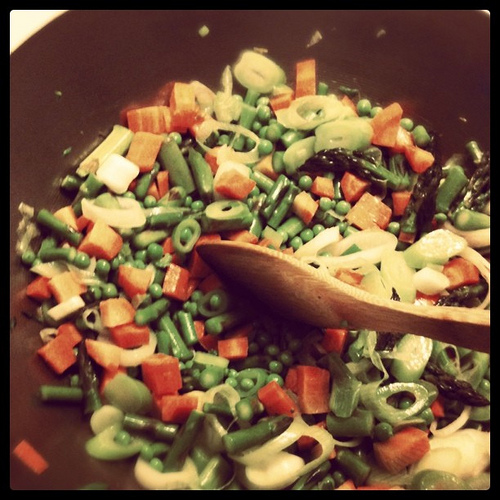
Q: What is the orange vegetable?
A: Carrot.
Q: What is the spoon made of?
A: Wood.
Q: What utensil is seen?
A: Wooden spatula.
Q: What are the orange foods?
A: Carrots.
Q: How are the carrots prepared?
A: Diced.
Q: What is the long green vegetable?
A: Green beans.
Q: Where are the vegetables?
A: Wok.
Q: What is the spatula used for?
A: Mixing the food.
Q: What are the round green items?
A: Peas.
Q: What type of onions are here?
A: Scallions.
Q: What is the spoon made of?
A: Wood.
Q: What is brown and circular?
A: The plate.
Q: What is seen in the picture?
A: Cut vegetables.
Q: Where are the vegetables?
A: In the pan.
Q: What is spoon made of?
A: Wood.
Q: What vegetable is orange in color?
A: Carrot.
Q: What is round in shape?
A: Peas.